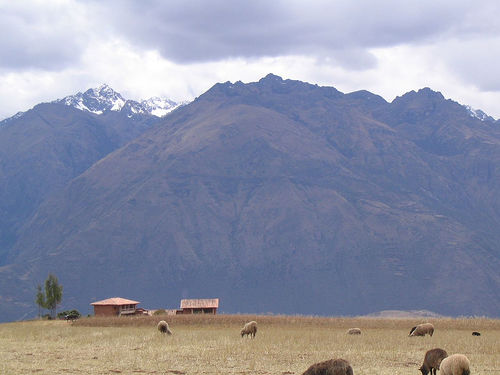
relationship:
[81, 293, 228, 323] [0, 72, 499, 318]
house near mountains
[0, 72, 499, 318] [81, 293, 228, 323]
mountains behind house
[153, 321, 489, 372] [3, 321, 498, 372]
sheep in grass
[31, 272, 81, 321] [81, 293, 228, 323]
tree behind house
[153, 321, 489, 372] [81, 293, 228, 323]
sheep near house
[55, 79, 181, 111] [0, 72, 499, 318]
snow on mountains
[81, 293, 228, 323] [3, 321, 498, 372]
house on grass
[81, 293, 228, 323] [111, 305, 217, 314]
house has windows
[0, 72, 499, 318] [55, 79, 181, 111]
mountains have snow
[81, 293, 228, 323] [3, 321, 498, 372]
house in grass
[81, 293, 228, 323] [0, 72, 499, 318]
house in front of mountains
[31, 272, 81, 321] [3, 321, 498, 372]
tree in grass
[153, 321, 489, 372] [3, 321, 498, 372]
sheep eating grass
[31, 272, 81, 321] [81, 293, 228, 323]
tree near house